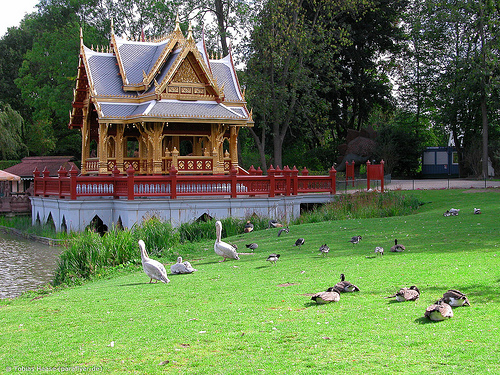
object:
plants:
[49, 230, 95, 278]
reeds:
[25, 221, 43, 236]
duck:
[307, 287, 341, 308]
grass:
[0, 186, 500, 375]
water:
[438, 0, 499, 181]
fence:
[114, 165, 300, 201]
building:
[421, 146, 461, 178]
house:
[64, 36, 253, 176]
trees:
[248, 18, 401, 144]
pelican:
[133, 238, 168, 284]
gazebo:
[78, 37, 260, 175]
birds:
[243, 207, 470, 323]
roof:
[112, 28, 224, 103]